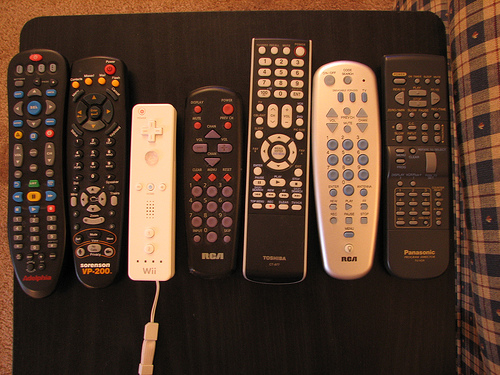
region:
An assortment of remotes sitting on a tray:
[3, 30, 484, 324]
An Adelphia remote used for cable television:
[5, 45, 67, 302]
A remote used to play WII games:
[125, 95, 178, 374]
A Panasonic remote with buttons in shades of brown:
[380, 50, 455, 283]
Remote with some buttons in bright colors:
[6, 45, 66, 301]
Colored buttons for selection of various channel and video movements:
[5, 44, 69, 299]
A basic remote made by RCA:
[181, 81, 238, 283]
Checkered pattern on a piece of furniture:
[441, 9, 499, 371]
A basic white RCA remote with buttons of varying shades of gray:
[313, 58, 380, 281]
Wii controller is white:
[130, 93, 195, 295]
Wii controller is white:
[111, 100, 180, 274]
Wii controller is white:
[111, 95, 192, 286]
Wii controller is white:
[109, 95, 174, 299]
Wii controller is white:
[124, 99, 191, 265]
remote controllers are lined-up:
[0, 36, 462, 305]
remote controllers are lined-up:
[8, 42, 452, 294]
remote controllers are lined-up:
[1, 33, 451, 305]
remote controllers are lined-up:
[5, 33, 463, 317]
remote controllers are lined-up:
[5, 40, 450, 336]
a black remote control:
[5, 50, 65, 300]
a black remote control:
[67, 55, 125, 289]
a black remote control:
[181, 86, 238, 281]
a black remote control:
[242, 35, 310, 287]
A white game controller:
[122, 95, 180, 373]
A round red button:
[215, 96, 236, 116]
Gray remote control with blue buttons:
[301, 50, 386, 285]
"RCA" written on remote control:
[190, 241, 230, 266]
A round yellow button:
[20, 185, 45, 205]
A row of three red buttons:
[185, 165, 235, 185]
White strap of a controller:
[130, 275, 167, 370]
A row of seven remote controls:
[0, 25, 461, 301]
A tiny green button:
[20, 171, 41, 191]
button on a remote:
[391, 188, 408, 233]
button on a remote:
[432, 187, 440, 229]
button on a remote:
[420, 150, 443, 175]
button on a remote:
[320, 135, 340, 185]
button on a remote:
[355, 130, 370, 185]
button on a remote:
[316, 98, 337, 133]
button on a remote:
[287, 58, 307, 98]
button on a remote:
[218, 181, 238, 228]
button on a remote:
[181, 183, 206, 238]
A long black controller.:
[6, 39, 68, 299]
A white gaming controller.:
[128, 87, 177, 373]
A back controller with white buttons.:
[242, 31, 309, 285]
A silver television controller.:
[308, 48, 372, 275]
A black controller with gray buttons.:
[376, 50, 454, 280]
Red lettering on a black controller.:
[13, 272, 53, 287]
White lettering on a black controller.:
[80, 259, 117, 269]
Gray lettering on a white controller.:
[137, 268, 164, 277]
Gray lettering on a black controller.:
[198, 246, 226, 263]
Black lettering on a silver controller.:
[342, 253, 358, 267]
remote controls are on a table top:
[0, 11, 460, 328]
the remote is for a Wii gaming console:
[129, 106, 173, 282]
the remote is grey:
[312, 66, 379, 276]